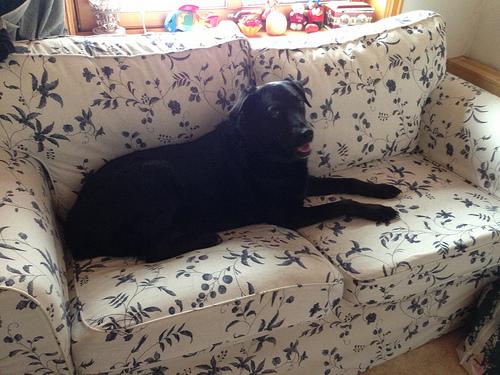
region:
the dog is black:
[32, 88, 384, 234]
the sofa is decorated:
[136, 260, 343, 331]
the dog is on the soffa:
[6, 46, 498, 326]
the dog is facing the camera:
[85, 63, 422, 254]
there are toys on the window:
[121, 10, 439, 38]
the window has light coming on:
[56, 2, 448, 53]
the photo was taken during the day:
[3, 6, 498, 367]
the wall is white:
[458, 16, 494, 46]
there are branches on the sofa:
[193, 258, 285, 308]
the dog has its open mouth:
[258, 106, 354, 177]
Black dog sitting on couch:
[90, 83, 380, 226]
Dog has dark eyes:
[265, 87, 329, 125]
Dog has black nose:
[287, 115, 340, 172]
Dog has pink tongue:
[290, 124, 332, 173]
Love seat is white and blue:
[31, 201, 311, 342]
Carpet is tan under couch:
[412, 298, 449, 360]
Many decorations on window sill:
[113, 13, 372, 42]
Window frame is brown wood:
[360, 2, 407, 25]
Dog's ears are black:
[221, 73, 361, 128]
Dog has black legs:
[321, 152, 405, 276]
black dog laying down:
[52, 74, 402, 236]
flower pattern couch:
[12, 32, 499, 357]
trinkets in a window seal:
[163, 1, 384, 29]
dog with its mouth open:
[244, 87, 323, 165]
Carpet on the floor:
[401, 339, 441, 374]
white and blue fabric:
[179, 268, 264, 342]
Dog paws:
[370, 170, 407, 233]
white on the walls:
[455, 1, 496, 52]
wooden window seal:
[382, 1, 398, 19]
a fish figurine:
[159, 4, 226, 37]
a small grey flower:
[383, 74, 401, 96]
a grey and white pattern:
[14, 61, 172, 136]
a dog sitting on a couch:
[24, 10, 474, 355]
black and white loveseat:
[24, 24, 489, 365]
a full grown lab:
[40, 79, 415, 249]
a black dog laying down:
[58, 74, 422, 261]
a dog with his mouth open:
[226, 72, 334, 170]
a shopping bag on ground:
[441, 264, 496, 374]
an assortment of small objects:
[156, 0, 375, 43]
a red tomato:
[297, 17, 329, 38]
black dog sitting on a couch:
[0, 7, 497, 371]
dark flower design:
[25, 65, 67, 115]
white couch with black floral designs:
[0, 7, 499, 373]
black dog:
[58, 72, 415, 272]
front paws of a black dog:
[312, 166, 415, 237]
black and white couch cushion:
[303, 152, 498, 287]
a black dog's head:
[236, 75, 323, 160]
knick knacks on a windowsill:
[35, 0, 411, 44]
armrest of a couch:
[0, 135, 102, 373]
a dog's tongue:
[295, 140, 314, 155]